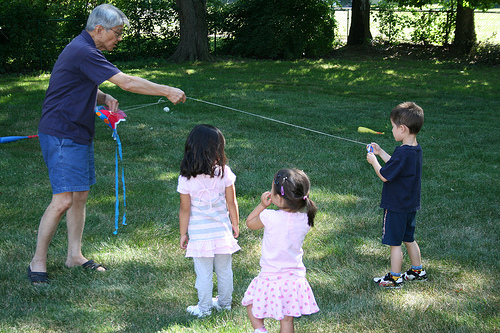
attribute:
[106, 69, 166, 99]
arm — bare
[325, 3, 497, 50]
fence — chain link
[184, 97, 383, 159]
string — thin, light blue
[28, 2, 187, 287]
man — older, old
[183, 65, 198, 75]
light — shining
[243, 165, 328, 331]
girl — little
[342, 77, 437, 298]
boy — young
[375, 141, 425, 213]
t-shirt — blue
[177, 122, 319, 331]
girls — little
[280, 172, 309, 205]
hair — brown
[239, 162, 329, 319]
girl — little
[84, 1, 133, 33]
hair — gray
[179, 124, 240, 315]
girl — little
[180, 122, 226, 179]
hair — black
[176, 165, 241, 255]
shirt — blue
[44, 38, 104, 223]
man — old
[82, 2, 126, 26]
hair — gray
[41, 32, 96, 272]
man — old